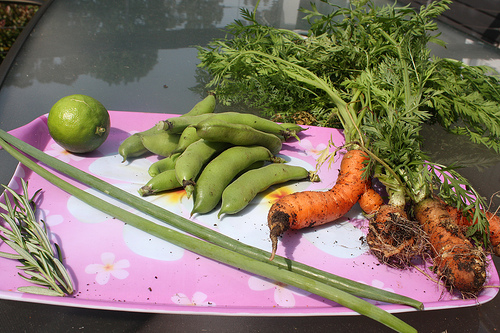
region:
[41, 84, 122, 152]
an orange in the plate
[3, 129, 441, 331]
two large size beans in the pink colour tray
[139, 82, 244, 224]
peas in the plate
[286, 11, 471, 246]
carrot with leaves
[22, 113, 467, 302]
green vegetables in the pink colour tray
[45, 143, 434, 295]
a pink colour plate with white colour flower design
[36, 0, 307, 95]
a shadow of the tree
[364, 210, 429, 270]
a roots of the carrot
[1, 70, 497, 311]
a plate kept on a table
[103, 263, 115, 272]
center of the flower is yellow colour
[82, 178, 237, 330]
the plate is pink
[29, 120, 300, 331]
the plate is pink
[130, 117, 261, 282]
the plate is pink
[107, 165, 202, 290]
the plate is pink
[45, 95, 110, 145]
green lime on serving tray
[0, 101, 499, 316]
pink and white serving tray with vegetables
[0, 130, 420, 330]
long skinny green vegetable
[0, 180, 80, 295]
green herb on tray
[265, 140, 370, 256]
bright orange carrot on tray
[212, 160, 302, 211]
green pea pod on tray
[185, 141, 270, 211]
pea pod next to pea pod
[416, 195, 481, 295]
dirty carrot on tray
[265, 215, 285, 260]
small root on carrot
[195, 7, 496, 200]
green leafy part of carrot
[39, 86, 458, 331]
pink plate on car hood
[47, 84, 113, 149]
green vegetable on plate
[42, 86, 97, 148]
green vegetable is round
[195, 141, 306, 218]
green pepper on plate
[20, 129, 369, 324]
green stalk-like vegetable on plate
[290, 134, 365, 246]
carrot-like vegetable on plate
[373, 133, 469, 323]
orange root vegetables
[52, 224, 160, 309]
flowers on pink plate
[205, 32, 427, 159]
herb-like plant on plate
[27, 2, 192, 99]
reflection of trees on surface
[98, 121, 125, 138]
tip of an orange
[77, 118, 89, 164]
part of an orange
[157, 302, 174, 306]
side of a tray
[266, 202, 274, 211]
part of dirty soil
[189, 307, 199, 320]
part of a table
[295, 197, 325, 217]
part of a carrot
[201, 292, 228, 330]
side of a tray